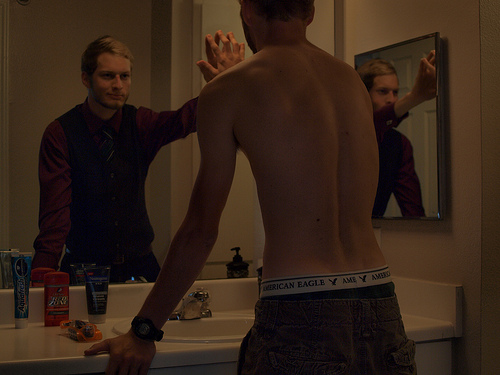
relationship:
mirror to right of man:
[343, 30, 457, 235] [31, 29, 253, 281]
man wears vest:
[40, 29, 172, 264] [57, 103, 154, 263]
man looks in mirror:
[83, 0, 419, 375] [14, 9, 363, 292]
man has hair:
[31, 33, 198, 283] [77, 30, 137, 65]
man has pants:
[83, 0, 433, 375] [233, 294, 417, 374]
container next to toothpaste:
[44, 271, 69, 326] [7, 248, 35, 330]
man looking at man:
[83, 0, 433, 375] [31, 33, 198, 283]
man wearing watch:
[83, 0, 433, 375] [118, 288, 169, 353]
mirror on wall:
[353, 31, 442, 219] [342, 1, 484, 331]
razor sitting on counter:
[53, 312, 110, 345] [2, 285, 454, 356]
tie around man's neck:
[94, 123, 121, 234] [84, 92, 146, 120]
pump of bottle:
[225, 243, 245, 256] [221, 241, 251, 279]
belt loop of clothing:
[353, 297, 380, 343] [226, 262, 425, 372]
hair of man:
[81, 34, 136, 74] [31, 33, 198, 283]